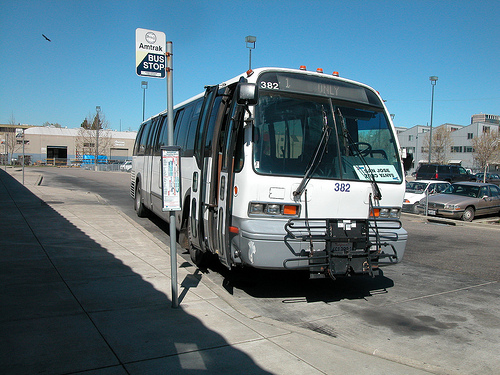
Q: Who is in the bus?
A: No one.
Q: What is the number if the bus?
A: 382.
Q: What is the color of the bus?
A: White.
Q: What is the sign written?
A: Bus stop.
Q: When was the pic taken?
A: During the day.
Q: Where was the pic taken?
A: On the road.